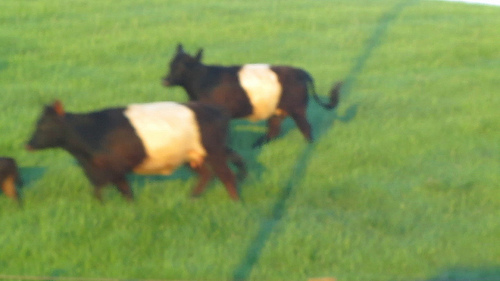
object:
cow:
[26, 99, 248, 202]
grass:
[0, 0, 500, 281]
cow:
[163, 41, 344, 151]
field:
[0, 0, 500, 281]